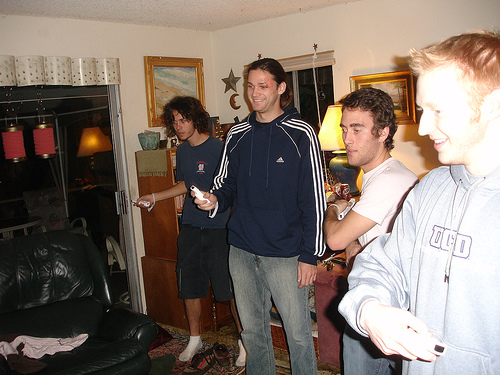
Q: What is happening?
A: They are playing games.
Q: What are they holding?
A: Controllers.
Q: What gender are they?
A: Males.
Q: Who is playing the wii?
A: Four men are playing.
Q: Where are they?
A: In a house.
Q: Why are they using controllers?
A: To play the Wii.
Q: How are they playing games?
A: With a controller.